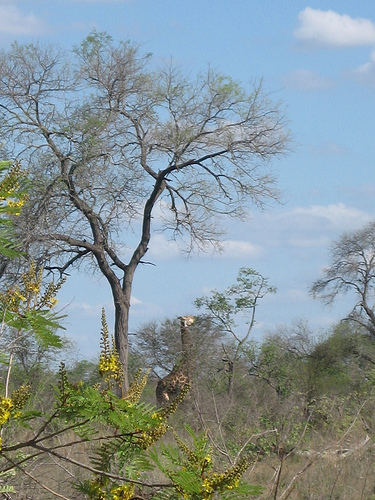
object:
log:
[245, 432, 372, 462]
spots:
[168, 380, 174, 386]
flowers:
[207, 484, 210, 490]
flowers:
[109, 364, 114, 371]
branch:
[197, 147, 228, 163]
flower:
[98, 305, 126, 402]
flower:
[203, 453, 212, 465]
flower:
[0, 395, 14, 426]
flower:
[199, 450, 245, 497]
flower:
[97, 482, 144, 500]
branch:
[39, 123, 64, 163]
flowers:
[137, 392, 142, 395]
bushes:
[357, 470, 370, 494]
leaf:
[166, 466, 206, 496]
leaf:
[21, 306, 65, 351]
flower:
[110, 332, 124, 388]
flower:
[201, 449, 262, 496]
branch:
[139, 145, 159, 179]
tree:
[190, 265, 278, 391]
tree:
[0, 153, 263, 500]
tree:
[246, 317, 365, 431]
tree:
[308, 219, 375, 340]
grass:
[0, 357, 370, 499]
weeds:
[302, 439, 305, 442]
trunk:
[112, 303, 130, 401]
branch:
[231, 330, 241, 343]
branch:
[167, 184, 186, 204]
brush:
[0, 310, 375, 500]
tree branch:
[0, 364, 259, 499]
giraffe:
[155, 314, 199, 414]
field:
[0, 356, 375, 499]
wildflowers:
[154, 413, 159, 420]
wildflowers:
[7, 401, 13, 411]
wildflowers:
[52, 297, 58, 304]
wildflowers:
[19, 201, 21, 205]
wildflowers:
[217, 480, 220, 484]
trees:
[13, 346, 27, 355]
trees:
[294, 348, 303, 362]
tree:
[0, 24, 295, 403]